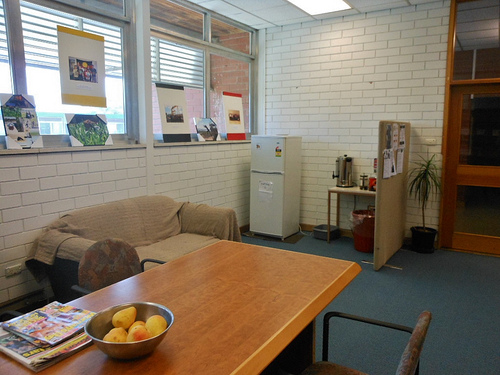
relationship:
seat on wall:
[24, 195, 241, 304] [10, 150, 288, 238]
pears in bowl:
[102, 307, 166, 343] [80, 328, 170, 353]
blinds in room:
[0, 0, 139, 141] [0, 2, 496, 371]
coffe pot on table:
[331, 153, 354, 188] [333, 184, 383, 254]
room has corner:
[0, 2, 496, 371] [401, 96, 445, 259]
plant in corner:
[409, 154, 441, 234] [401, 96, 445, 259]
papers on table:
[0, 294, 95, 374] [2, 239, 360, 371]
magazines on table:
[7, 295, 92, 342] [2, 239, 360, 371]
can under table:
[346, 198, 381, 264] [329, 182, 378, 258]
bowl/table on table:
[85, 293, 212, 370] [66, 340, 266, 373]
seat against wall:
[71, 201, 166, 261] [2, 150, 300, 211]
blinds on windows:
[0, 4, 208, 89] [0, 0, 255, 140]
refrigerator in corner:
[250, 134, 303, 241] [249, 23, 296, 246]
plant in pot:
[401, 152, 449, 232] [408, 230, 439, 260]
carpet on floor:
[400, 274, 475, 311] [343, 242, 481, 365]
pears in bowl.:
[94, 300, 166, 341] [80, 300, 180, 346]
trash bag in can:
[344, 199, 390, 271] [351, 206, 371, 249]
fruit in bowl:
[95, 306, 152, 340] [80, 298, 177, 360]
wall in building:
[270, 25, 439, 225] [0, 4, 449, 269]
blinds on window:
[148, 31, 215, 88] [145, 1, 210, 141]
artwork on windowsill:
[59, 49, 106, 86] [6, 4, 157, 154]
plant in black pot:
[401, 152, 449, 232] [402, 222, 437, 252]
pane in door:
[457, 93, 497, 169] [436, 5, 499, 256]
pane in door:
[456, 183, 496, 232] [436, 5, 499, 256]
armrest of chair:
[317, 308, 413, 360] [320, 302, 440, 369]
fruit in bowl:
[102, 306, 167, 343] [72, 297, 184, 360]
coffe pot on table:
[332, 154, 354, 188] [319, 168, 381, 244]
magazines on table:
[0, 300, 96, 372] [13, 230, 363, 365]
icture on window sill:
[66, 110, 118, 147] [24, 7, 153, 154]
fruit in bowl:
[102, 306, 167, 343] [121, 339, 148, 361]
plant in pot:
[401, 152, 449, 232] [411, 219, 438, 256]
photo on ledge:
[0, 93, 43, 153] [208, 133, 261, 146]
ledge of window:
[208, 133, 261, 146] [205, 14, 257, 57]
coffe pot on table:
[332, 154, 354, 188] [189, 260, 274, 312]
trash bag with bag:
[350, 209, 375, 253] [352, 210, 374, 223]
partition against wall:
[367, 115, 415, 271] [258, 33, 439, 238]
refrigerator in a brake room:
[245, 131, 302, 241] [2, 1, 498, 371]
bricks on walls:
[284, 84, 349, 117] [284, 37, 420, 110]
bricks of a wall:
[266, 0, 450, 237] [269, 29, 429, 114]